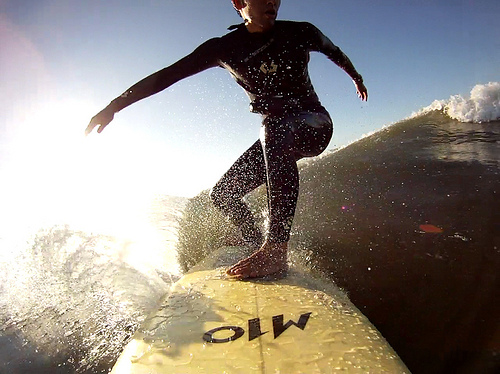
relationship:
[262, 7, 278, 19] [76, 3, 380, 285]
mouth of man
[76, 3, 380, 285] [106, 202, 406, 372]
man standing on surfboard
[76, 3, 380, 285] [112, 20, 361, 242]
man wearing wet suit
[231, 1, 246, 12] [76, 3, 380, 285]
ear of man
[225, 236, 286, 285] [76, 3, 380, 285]
foot of man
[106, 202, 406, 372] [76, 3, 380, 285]
surfboard under man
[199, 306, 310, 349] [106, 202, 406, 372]
m10 on surfboard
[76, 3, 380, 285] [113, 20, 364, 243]
man wearing wetsuit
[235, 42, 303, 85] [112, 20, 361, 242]
logo on wet suit